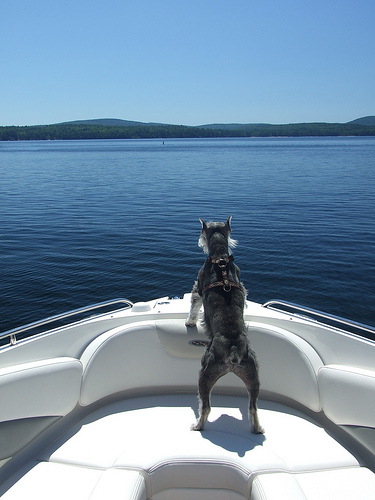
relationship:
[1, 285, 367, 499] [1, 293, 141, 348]
boat has silver railing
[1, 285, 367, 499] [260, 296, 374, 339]
boat has silver railing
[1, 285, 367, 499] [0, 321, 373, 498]
boat has white cushions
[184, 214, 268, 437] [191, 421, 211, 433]
dog has gray foot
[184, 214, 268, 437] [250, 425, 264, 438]
dog has gray foot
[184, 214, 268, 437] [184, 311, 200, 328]
dog has gray foot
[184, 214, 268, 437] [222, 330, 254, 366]
dog has gray tail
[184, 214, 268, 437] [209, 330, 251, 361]
dog has gray butt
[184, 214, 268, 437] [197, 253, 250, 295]
dog has brown harness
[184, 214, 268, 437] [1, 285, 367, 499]
dog standing on back of boat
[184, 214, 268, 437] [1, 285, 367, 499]
dog standing on boat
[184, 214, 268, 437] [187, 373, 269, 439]
dog standing on back legs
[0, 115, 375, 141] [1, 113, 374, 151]
mountain top on horizon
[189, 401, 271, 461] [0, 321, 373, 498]
dog shadow on cushion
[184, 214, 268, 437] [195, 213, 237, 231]
dog has pointy ears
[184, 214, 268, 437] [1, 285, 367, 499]
dog perched on boat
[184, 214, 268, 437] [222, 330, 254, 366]
dog has small tail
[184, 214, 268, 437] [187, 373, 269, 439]
dog has back legs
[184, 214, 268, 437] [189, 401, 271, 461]
dog has dog shadow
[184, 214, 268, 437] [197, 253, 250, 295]
dog wearing brown harness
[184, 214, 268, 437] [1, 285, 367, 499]
dog leaning on boat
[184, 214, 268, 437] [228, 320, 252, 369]
dog has clipped tail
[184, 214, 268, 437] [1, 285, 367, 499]
dog on bow of boat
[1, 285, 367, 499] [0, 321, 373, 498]
boat has bow white cushions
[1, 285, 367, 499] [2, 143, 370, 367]
boat bow running light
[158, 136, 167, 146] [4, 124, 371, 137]
buoy in distance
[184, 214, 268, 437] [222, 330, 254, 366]
dog has stubby tail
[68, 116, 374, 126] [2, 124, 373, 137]
hills beyond trees